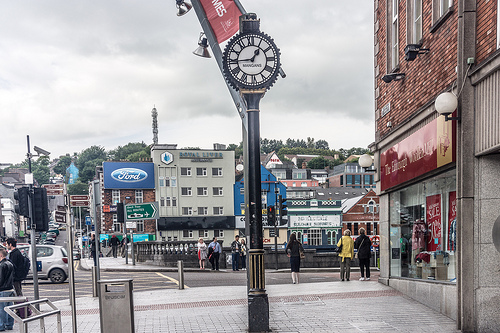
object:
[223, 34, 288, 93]
clock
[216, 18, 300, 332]
pole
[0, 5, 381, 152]
sky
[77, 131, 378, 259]
buildings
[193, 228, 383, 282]
people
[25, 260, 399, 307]
street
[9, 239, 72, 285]
car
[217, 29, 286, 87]
clock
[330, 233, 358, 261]
jacket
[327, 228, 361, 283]
person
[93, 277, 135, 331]
trash container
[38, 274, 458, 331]
sidewalk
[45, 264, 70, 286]
wheel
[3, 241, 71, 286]
vehicle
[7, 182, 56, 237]
signal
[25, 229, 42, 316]
pole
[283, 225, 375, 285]
people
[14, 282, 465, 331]
sidewalk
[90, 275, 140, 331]
trash